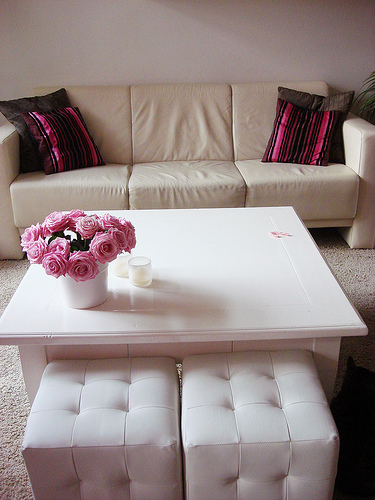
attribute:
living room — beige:
[3, 78, 375, 246]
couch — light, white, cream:
[3, 74, 375, 253]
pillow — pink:
[266, 96, 346, 162]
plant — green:
[354, 68, 375, 126]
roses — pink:
[20, 211, 131, 284]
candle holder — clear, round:
[128, 254, 153, 292]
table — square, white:
[1, 203, 372, 358]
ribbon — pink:
[270, 226, 293, 244]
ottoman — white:
[180, 348, 344, 499]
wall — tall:
[4, 1, 372, 83]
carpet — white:
[341, 249, 369, 287]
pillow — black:
[276, 87, 356, 102]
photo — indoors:
[1, 2, 375, 499]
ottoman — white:
[21, 353, 180, 498]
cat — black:
[334, 355, 374, 483]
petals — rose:
[268, 230, 300, 238]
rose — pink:
[91, 234, 119, 267]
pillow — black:
[1, 90, 73, 121]